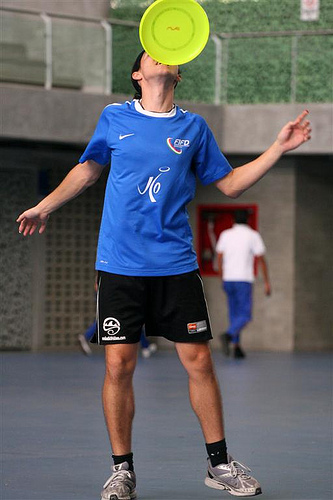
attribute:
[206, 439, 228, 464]
black sock — one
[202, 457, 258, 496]
sneaker — grey, white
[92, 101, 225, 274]
blue shirt — short sleeved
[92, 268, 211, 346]
black shorts — blue, sports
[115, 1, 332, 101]
green hedge — row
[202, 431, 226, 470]
sock — black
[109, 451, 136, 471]
sock — black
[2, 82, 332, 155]
wall — cement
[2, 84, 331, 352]
wall — grey, cement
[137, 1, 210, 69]
frisbee — yellow, bright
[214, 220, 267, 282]
shirt — white, short sleeved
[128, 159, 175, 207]
design — white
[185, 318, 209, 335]
tag — red, grey, black, white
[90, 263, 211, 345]
shorts — black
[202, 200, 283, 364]
image — blurry